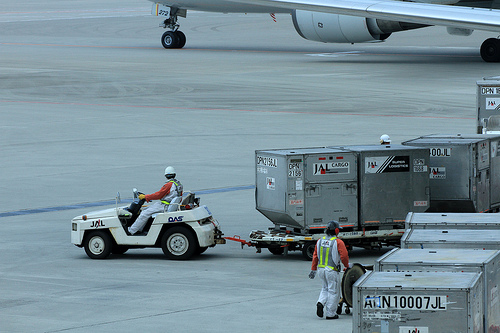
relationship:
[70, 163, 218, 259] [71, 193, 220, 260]
man riding white truck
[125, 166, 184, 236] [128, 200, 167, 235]
man wearing white pants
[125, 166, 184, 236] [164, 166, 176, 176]
man wearing hat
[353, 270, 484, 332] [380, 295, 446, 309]
silver tank has writing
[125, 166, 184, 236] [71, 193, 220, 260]
man driving car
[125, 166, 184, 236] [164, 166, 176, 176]
man wearing helmet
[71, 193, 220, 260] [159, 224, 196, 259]
car has wheel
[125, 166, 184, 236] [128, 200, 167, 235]
man wears pants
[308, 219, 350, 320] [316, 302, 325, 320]
man wears shoes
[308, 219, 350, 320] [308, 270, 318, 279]
man has hand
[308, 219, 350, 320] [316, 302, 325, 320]
man has shoes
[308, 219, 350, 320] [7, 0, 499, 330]
man at airport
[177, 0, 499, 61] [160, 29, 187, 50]
plane has wheel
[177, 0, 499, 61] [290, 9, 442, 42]
plane has engine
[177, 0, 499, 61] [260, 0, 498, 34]
plane has wing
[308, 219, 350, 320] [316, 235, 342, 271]
man has vest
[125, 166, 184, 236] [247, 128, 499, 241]
man tows luggage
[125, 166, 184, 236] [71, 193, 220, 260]
man in cart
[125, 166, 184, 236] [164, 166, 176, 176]
man has hat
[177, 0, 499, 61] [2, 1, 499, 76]
plane on cement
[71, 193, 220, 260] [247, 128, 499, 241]
cart pulls canisters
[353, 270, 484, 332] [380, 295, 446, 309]
canister has stickers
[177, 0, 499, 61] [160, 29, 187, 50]
airplane has wheels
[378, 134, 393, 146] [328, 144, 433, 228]
person behind canister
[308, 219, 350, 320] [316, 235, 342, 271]
man wearing vest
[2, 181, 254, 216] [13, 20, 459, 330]
line on road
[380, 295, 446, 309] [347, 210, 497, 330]
number on tank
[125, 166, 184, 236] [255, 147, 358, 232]
man pulling container